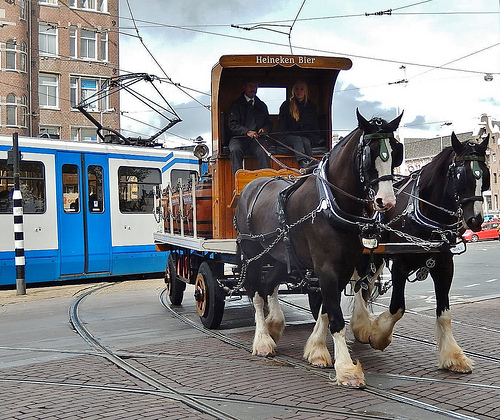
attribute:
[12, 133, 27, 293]
pole — black, white, striped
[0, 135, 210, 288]
train — blue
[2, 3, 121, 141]
brown building — behind train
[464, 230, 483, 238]
car — RED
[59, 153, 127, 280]
doors — of transit system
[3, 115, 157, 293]
transit system — public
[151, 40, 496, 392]
carriage — carrying two people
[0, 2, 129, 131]
building — in the sky, brick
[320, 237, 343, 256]
skin — of a horse, white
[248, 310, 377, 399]
feet — hairy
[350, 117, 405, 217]
face — horses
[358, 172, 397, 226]
bridle — on the face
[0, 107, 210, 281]
train — blue, white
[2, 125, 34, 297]
sign pole — white, black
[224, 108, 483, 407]
horses — brown, white